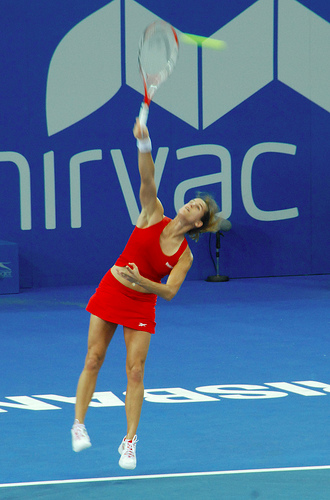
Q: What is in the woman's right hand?
A: A tennis racket.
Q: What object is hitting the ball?
A: A racket.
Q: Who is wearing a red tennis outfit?
A: The woman tennis player.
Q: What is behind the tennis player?
A: Advertisement.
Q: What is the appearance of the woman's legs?
A: Very toned.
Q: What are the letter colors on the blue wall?
A: White.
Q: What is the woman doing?
A: Playing tennis.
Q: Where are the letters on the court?
A: Behind the woman.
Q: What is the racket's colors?
A: Red and white.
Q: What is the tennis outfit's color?
A: Red.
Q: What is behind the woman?
A: A blue and white wall.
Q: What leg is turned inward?
A: The right leg.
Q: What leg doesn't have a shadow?
A: The left leg.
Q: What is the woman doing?
A: Playing tennis.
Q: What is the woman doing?
A: Jumping to hit the ball.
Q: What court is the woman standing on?
A: A blue court.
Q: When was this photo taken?
A: Daytime.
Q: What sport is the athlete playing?
A: Tennis.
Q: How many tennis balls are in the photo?
A: One.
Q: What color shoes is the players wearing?
A: White.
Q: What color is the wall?
A: Blue.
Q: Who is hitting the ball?
A: The tennis player.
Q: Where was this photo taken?
A: A tennis court.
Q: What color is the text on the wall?
A: White.